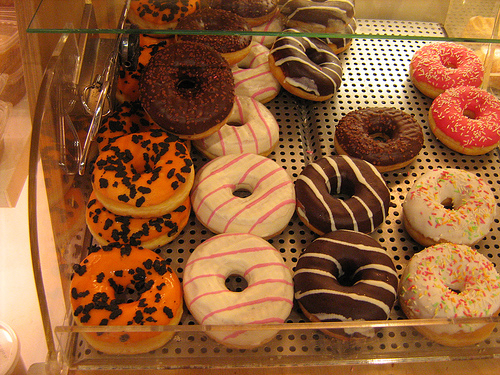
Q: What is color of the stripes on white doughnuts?
A: Pink.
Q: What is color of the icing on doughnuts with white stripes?
A: Brown.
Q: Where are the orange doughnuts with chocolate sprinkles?
A: At the left side.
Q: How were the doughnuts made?
A: Fried.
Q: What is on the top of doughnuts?
A: Icing.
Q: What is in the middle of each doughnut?
A: A hole.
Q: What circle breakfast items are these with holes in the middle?
A: Donuts.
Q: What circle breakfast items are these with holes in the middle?
A: Donuts.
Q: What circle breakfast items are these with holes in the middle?
A: Donuts.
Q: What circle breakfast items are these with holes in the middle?
A: Donuts.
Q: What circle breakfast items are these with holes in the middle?
A: Donuts.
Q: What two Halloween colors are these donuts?
A: Orange and black.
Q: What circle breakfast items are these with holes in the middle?
A: Donuts.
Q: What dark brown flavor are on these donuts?
A: Chocolate.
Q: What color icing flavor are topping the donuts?
A: Vanilla.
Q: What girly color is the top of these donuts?
A: Pink.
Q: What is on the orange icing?
A: Chocolate sprinkles.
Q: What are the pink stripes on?
A: White frosted doughnut.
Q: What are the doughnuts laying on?
A: Shelf.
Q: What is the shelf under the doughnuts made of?
A: Metal.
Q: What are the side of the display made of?
A: Glass.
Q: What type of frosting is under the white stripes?
A: Chocolate.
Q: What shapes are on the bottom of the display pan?
A: Circles.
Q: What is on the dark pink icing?
A: White sprinkles.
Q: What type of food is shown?
A: Pastry.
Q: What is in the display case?
A: Doughnuts.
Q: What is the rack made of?
A: Glass.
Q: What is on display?
A: Assorted doughnuts.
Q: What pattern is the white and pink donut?
A: Striped.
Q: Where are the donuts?
A: In a case.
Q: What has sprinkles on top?
A: Donuts.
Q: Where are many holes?
A: In the donuts.